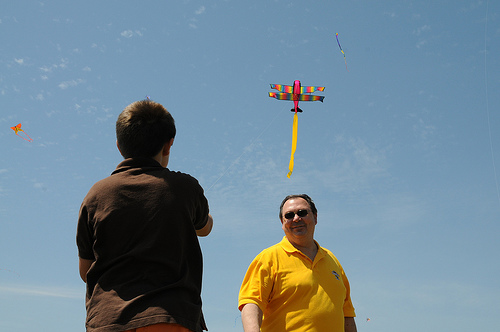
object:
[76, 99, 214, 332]
boy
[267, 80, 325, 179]
kite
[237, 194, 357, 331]
man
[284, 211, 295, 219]
eyes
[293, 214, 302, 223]
nose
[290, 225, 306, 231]
mouth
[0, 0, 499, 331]
sky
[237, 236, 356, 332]
shirt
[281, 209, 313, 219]
glasses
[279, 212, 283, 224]
ears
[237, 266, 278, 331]
arms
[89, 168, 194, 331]
brown